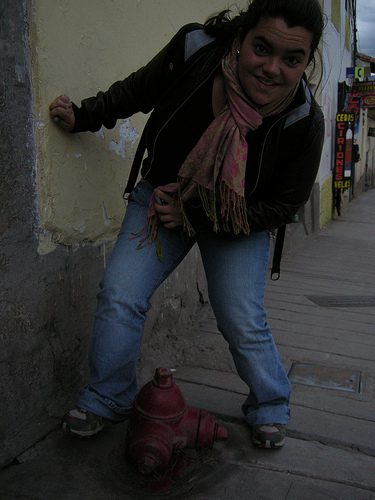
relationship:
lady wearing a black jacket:
[50, 2, 323, 450] [71, 21, 325, 241]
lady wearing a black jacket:
[53, 2, 355, 467] [71, 21, 325, 241]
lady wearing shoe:
[50, 2, 323, 450] [244, 413, 291, 453]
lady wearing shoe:
[50, 2, 323, 450] [55, 396, 129, 437]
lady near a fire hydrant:
[50, 2, 323, 450] [106, 362, 232, 498]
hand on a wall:
[49, 94, 74, 131] [1, 2, 354, 465]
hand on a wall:
[152, 185, 182, 231] [1, 2, 354, 465]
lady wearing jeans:
[50, 2, 323, 450] [73, 173, 301, 453]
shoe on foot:
[251, 423, 287, 451] [244, 391, 288, 451]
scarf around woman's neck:
[155, 83, 273, 226] [213, 59, 303, 106]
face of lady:
[236, 3, 324, 105] [50, 2, 323, 450]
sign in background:
[335, 124, 348, 190] [308, 34, 374, 222]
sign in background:
[340, 62, 367, 81] [308, 34, 374, 222]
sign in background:
[345, 89, 362, 127] [308, 34, 374, 222]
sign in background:
[362, 98, 374, 109] [308, 34, 374, 222]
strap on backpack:
[265, 222, 291, 282] [127, 44, 230, 144]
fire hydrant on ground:
[116, 362, 233, 492] [0, 193, 368, 492]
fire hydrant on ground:
[125, 362, 229, 499] [307, 241, 371, 368]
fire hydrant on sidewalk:
[125, 362, 229, 499] [7, 183, 371, 498]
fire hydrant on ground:
[125, 362, 229, 499] [0, 193, 368, 492]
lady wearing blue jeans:
[50, 2, 323, 450] [91, 186, 322, 387]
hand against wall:
[46, 90, 86, 139] [2, 0, 332, 498]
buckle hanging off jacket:
[266, 219, 289, 283] [67, 13, 326, 250]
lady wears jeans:
[50, 2, 323, 450] [53, 5, 337, 454]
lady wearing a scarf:
[50, 2, 323, 450] [129, 35, 300, 259]